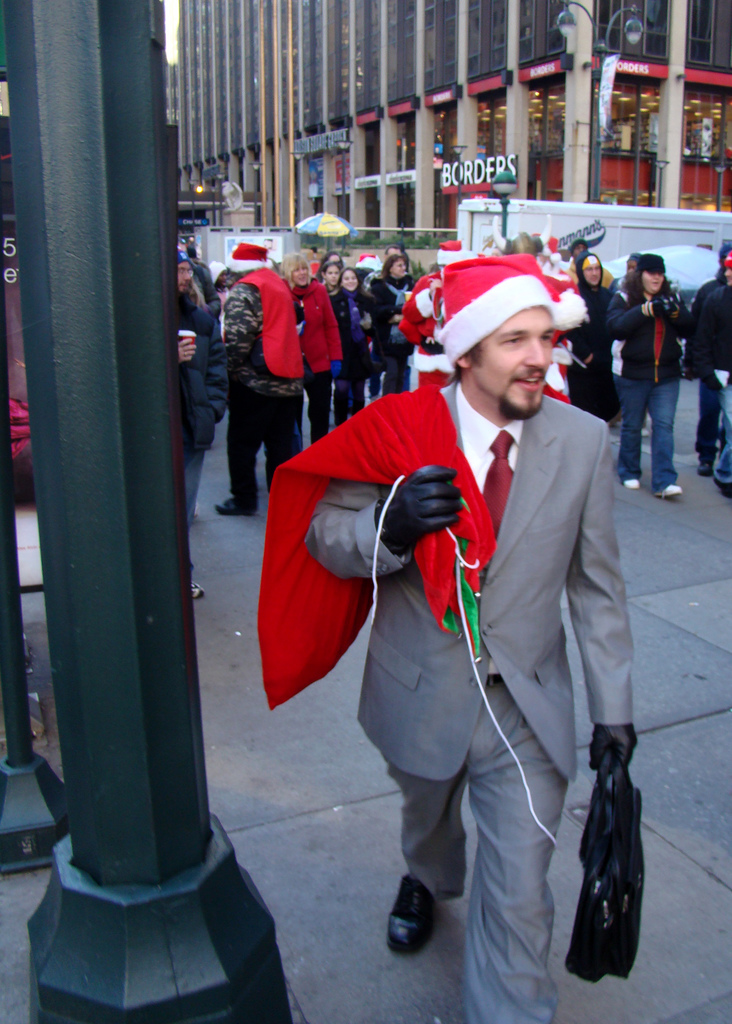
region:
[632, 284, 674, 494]
the person is standing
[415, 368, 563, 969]
the person is standing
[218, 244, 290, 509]
the person is standing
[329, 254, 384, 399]
the person is standing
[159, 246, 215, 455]
the person is standing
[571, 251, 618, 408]
the person is standing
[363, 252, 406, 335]
the person is standing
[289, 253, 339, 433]
the person is standing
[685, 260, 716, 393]
the person is standing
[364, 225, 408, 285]
the person is standing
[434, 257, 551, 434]
the head of a man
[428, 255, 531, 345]
the hat of a man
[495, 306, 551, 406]
the face of a man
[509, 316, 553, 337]
the eyebrows of a man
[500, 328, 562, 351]
the eyes of a man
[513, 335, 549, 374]
the nose of a man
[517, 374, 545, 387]
the mouth of a man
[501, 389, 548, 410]
the chin of a man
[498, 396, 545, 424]
the beard of a man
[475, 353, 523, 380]
the cheek of a man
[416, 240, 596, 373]
red and white santa hat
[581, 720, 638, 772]
black glove on the hand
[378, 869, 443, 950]
black leather shoe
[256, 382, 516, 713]
red sack hanging over the arm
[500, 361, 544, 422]
goatee on the face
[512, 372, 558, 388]
mouth is slightly open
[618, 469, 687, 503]
a pair of white shoes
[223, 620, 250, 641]
white speck on the ground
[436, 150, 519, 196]
Borders logo on the side of the building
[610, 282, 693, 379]
black jacket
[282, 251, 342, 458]
Woman with blond hair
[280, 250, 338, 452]
Woman is wearing a red jacket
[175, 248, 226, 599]
Man is holding a cup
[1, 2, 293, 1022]
Big pole is black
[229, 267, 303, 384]
Man in a red cap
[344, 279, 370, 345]
Woman has a purple scarf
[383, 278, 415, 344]
Woman has a blue scarf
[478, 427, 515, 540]
Man has a red tie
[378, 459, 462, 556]
Man has a black glove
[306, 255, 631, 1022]
Man is hearing a grey suit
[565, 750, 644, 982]
Man is holding a black bag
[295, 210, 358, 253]
A blue and yellow umbrella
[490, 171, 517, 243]
Green and white lamp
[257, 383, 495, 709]
Man is holding a red bag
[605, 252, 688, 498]
Woman is wearing a black jacket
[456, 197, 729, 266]
White truck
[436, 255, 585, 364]
Red and white santa hat on a grey suit man.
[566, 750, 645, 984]
Black bag a man in a grey suit is holding.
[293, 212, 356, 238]
Blue and yellow umbrella top.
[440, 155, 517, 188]
Large white word BORDERS.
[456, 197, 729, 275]
Large white long truck.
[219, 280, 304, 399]
Camoflauge coat on a man with a red bag.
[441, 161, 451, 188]
Largest B in the word BORDERS.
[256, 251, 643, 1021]
man wearing a Santa hat and carrying a red bag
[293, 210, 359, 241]
blue and yellow umbrella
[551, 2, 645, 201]
a double street lamp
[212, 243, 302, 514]
man wearing a Santa hat and red cape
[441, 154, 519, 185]
business sign with large white letters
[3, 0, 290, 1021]
tall black metal pole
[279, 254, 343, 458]
blond woman wearing a red coat and blue gloves